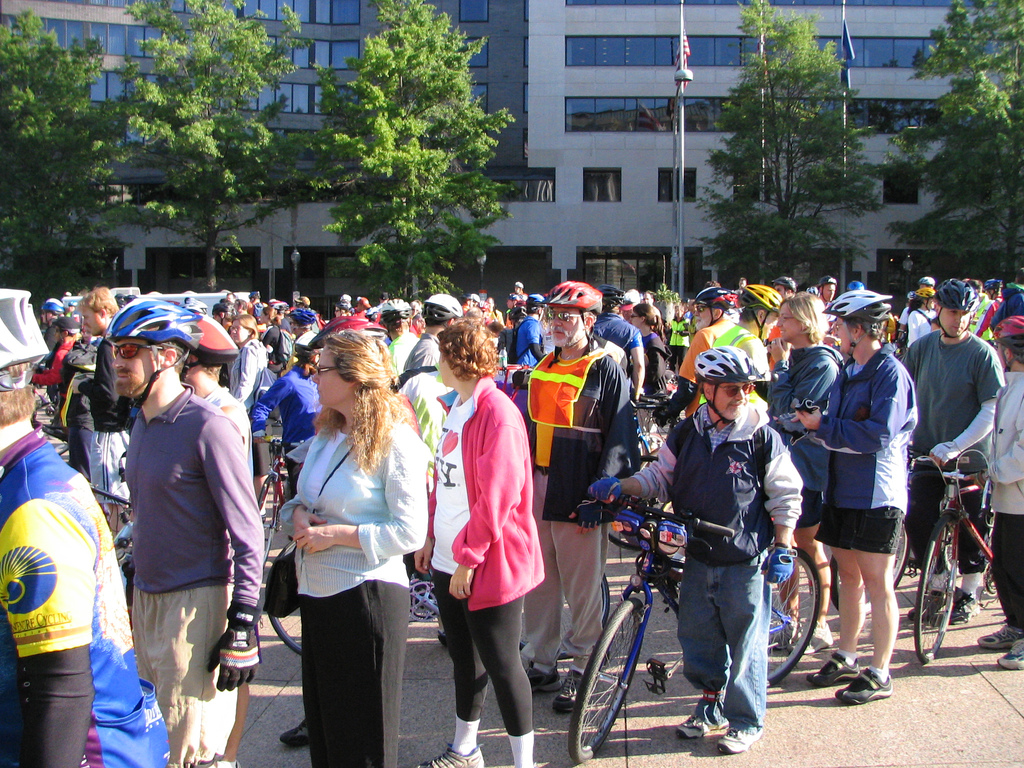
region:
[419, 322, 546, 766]
a woman is walking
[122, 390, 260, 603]
the shirt is purple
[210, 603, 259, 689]
glove on the hand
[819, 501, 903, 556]
the shorts are black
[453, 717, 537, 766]
the socks are white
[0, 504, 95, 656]
the sleeve is yellow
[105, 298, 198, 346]
helmet on the head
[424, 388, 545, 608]
the woman wears a pink sweater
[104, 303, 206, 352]
the man wears a helmet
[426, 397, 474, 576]
the woman wears i love ny shirt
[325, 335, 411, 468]
the woman has long hair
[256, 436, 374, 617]
the woman carries a purse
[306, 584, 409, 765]
the woman wears black bottoms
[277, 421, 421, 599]
the woman wears a button down shirt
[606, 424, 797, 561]
the man wears a jacket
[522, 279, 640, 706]
a man in a construction vest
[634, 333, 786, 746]
A person is standing up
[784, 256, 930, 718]
A person is standing up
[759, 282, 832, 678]
A person is standing up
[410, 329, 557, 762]
A person is standing up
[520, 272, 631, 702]
A person is standing up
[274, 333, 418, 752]
A person is standing up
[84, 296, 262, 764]
A person is standing up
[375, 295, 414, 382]
A person is standing up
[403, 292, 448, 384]
A person is standing up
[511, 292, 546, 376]
A person is standing up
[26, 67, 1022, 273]
The building in the background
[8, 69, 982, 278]
A building in the background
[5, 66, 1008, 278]
The trees in front of the building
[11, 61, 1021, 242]
A set of trees in front of the building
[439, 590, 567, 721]
woman wearing black leggings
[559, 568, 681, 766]
large wheel on bike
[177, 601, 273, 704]
black glove on hand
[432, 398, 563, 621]
sleeve of pink jacket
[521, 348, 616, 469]
yellow and orange safety vest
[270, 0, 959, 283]
tall white and gray office building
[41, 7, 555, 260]
tall green trees in front of building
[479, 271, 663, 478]
man has red helmet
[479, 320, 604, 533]
orange and yellow vest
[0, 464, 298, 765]
blue and yellow vest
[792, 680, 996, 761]
sidewalk is dark tan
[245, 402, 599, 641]
woman has pink shirt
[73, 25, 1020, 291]
tall and green trees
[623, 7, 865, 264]
flags on poles near trees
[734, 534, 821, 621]
man on bike has blue gloves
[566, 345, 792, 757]
a man standing next to a bike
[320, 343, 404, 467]
a woman with long hair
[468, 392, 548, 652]
a woman wearing a pink coat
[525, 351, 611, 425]
a man wearing a safety vest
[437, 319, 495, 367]
a woman with red hair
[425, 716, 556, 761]
a woman wearing white socks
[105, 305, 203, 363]
a mane wearing a blue and silver helmet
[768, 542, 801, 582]
a man wearing blue gloves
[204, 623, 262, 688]
a man wearing black gloves with stripes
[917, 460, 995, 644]
a red bicycle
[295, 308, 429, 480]
A woman has long blonde hair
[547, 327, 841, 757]
A guy holding a bicycle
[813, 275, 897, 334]
A black and white helmet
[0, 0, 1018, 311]
A row of green trees